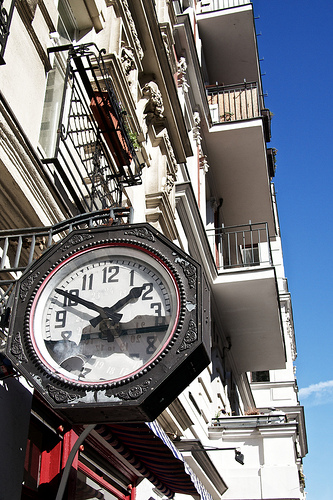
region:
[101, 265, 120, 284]
The number 12.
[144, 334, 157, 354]
The number eight on a clock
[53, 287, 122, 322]
Big hand of a clock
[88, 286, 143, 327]
A smaller black hand of a clock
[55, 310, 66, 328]
The black number 9 on a clock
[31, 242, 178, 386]
A black and white clock.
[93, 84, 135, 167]
An orange colored flower box above the clock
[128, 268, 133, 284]
The black number 1 on a clock by the 2 and 12.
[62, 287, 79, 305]
Number 10 on the clock obstructed by the large hand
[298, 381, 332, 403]
Thin white cloud in the sky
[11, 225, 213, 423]
white and black clock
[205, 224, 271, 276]
black iron patio railing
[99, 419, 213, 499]
blue and white awning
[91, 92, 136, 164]
orange terra cotta planter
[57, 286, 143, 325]
black hands on clock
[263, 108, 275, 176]
brown planters on railing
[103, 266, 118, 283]
black twelve on clock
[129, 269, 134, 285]
black one on clock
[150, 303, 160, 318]
black three on clock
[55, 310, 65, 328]
black nine on clock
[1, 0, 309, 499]
the tall building structure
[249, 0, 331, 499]
the blue sky with very little clouds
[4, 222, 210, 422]
the clock sticking out from the building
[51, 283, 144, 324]
the hands on the clock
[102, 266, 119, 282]
the 12 on the clock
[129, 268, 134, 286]
the 1 on the clock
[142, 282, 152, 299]
the 2 on the clock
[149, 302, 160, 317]
the 3 on the clock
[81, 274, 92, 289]
the 11 on the clock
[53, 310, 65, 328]
the 9 on the clock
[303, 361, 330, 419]
part of a cloud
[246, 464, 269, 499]
part of a cloth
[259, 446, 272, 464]
part fo a wall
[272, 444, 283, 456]
part of a pillar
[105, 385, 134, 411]
edge of a clock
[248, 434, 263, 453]
part fo a wall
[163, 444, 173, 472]
edge of a roof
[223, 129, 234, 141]
part of a surface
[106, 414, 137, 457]
edge of a clock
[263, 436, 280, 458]
part fo a wall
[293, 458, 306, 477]
dge fo a tower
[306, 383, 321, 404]
part of a cloud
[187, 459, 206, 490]
edge fo a building